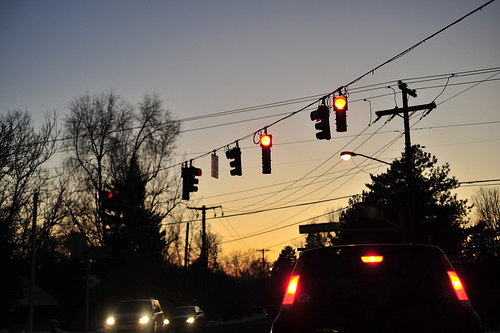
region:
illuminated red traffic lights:
[97, 87, 349, 213]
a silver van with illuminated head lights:
[103, 294, 163, 330]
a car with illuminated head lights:
[161, 302, 206, 332]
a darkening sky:
[6, 3, 493, 273]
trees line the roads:
[7, 90, 498, 322]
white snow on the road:
[199, 303, 269, 328]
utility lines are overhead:
[0, 64, 499, 258]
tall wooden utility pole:
[187, 203, 221, 268]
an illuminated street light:
[337, 147, 389, 167]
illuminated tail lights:
[266, 243, 488, 332]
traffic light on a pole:
[330, 87, 355, 133]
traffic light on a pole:
[301, 100, 329, 145]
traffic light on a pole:
[250, 111, 280, 183]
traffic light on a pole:
[218, 135, 248, 182]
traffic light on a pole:
[172, 155, 199, 203]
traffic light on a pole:
[90, 185, 125, 212]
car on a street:
[105, 298, 163, 329]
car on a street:
[165, 291, 222, 329]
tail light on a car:
[275, 265, 310, 316]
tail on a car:
[442, 259, 478, 300]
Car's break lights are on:
[280, 247, 475, 320]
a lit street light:
[327, 138, 416, 191]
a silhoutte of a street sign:
[290, 209, 390, 249]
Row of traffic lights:
[35, 78, 397, 210]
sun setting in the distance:
[0, 0, 497, 302]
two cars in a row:
[92, 287, 207, 331]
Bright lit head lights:
[102, 309, 153, 331]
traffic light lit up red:
[329, 91, 355, 137]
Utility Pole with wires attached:
[360, 74, 444, 217]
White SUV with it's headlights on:
[95, 288, 165, 330]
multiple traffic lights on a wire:
[59, 1, 496, 229]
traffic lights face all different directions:
[92, 85, 349, 220]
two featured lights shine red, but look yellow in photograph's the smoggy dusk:
[252, 76, 354, 188]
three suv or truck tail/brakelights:
[252, 202, 491, 330]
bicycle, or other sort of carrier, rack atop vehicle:
[288, 215, 458, 239]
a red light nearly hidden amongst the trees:
[97, 184, 123, 211]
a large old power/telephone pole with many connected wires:
[362, 68, 466, 193]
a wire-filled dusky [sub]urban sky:
[0, 2, 495, 249]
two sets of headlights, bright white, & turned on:
[83, 288, 209, 329]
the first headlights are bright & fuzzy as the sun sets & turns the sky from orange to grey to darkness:
[94, 306, 163, 331]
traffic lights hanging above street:
[161, 80, 359, 197]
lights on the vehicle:
[235, 250, 477, 315]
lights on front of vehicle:
[102, 313, 162, 332]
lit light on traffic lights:
[329, 95, 354, 106]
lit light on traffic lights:
[257, 133, 277, 145]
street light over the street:
[335, 143, 359, 164]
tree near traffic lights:
[354, 132, 478, 251]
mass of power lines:
[88, 85, 448, 217]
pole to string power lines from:
[361, 80, 426, 155]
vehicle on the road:
[163, 305, 208, 330]